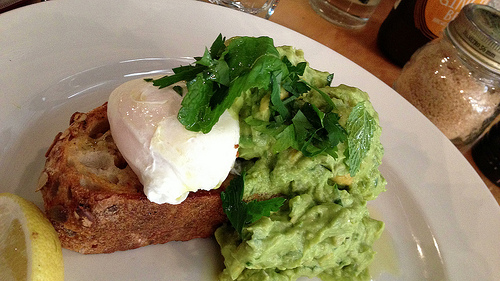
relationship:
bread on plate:
[58, 134, 111, 230] [78, 10, 144, 35]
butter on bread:
[107, 74, 242, 205] [58, 134, 111, 230]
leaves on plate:
[219, 49, 284, 95] [78, 10, 144, 35]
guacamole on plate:
[283, 191, 334, 242] [78, 10, 144, 35]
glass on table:
[316, 0, 376, 30] [356, 48, 367, 60]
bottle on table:
[377, 10, 394, 63] [356, 48, 367, 60]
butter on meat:
[152, 178, 184, 202] [272, 204, 327, 237]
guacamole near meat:
[283, 191, 334, 242] [272, 204, 327, 237]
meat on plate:
[272, 204, 327, 237] [78, 10, 144, 35]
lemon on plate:
[7, 208, 55, 254] [78, 10, 144, 35]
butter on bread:
[152, 178, 184, 202] [58, 134, 111, 230]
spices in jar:
[449, 107, 480, 129] [411, 35, 475, 135]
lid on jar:
[467, 0, 489, 35] [411, 35, 475, 135]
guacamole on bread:
[283, 191, 334, 242] [58, 134, 111, 230]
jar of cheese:
[411, 35, 475, 135] [441, 60, 478, 85]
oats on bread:
[89, 125, 101, 140] [58, 134, 111, 230]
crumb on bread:
[233, 144, 241, 154] [58, 134, 111, 230]